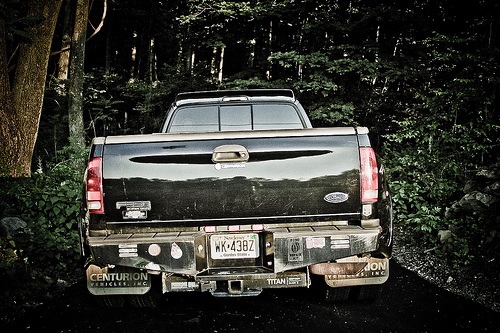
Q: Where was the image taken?
A: It was taken at the forest.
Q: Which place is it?
A: It is a forest.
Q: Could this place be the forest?
A: Yes, it is the forest.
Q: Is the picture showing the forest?
A: Yes, it is showing the forest.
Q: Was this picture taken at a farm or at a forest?
A: It was taken at a forest.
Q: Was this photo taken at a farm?
A: No, the picture was taken in a forest.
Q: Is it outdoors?
A: Yes, it is outdoors.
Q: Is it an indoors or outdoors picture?
A: It is outdoors.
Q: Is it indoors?
A: No, it is outdoors.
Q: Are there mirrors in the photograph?
A: No, there are no mirrors.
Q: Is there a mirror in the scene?
A: No, there are no mirrors.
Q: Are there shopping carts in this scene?
A: No, there are no shopping carts.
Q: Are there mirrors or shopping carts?
A: No, there are no shopping carts or mirrors.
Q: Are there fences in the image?
A: No, there are no fences.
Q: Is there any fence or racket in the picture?
A: No, there are no fences or rackets.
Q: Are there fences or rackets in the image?
A: No, there are no fences or rackets.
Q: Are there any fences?
A: No, there are no fences.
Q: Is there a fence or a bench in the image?
A: No, there are no fences or benches.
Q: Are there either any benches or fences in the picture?
A: No, there are no fences or benches.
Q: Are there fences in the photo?
A: No, there are no fences.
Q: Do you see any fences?
A: No, there are no fences.